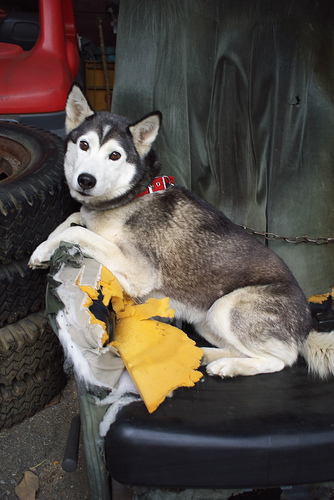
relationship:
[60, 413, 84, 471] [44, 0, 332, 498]
arm on chair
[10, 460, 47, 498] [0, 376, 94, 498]
leaf on ground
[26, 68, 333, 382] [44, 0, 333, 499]
dog on chair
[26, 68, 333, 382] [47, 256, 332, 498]
dog sitting on chair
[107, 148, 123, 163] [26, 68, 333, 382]
eye of dog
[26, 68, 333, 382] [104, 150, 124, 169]
dog has eye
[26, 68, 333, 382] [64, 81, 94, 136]
dog has dog's ear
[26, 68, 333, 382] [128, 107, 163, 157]
dog has ear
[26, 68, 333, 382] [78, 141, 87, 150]
dog has right eye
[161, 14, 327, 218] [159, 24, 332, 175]
shape on wall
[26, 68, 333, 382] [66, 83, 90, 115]
dog has ear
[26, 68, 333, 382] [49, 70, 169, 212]
dog has head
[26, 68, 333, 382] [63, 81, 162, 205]
dog has head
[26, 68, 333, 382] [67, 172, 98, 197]
dog has mouth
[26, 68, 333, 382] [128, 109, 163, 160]
dog has dog's ear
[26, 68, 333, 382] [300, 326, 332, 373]
dog has tail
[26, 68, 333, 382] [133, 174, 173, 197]
dog wearing collar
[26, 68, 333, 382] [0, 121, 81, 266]
dog near tire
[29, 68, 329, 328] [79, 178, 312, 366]
dog has body